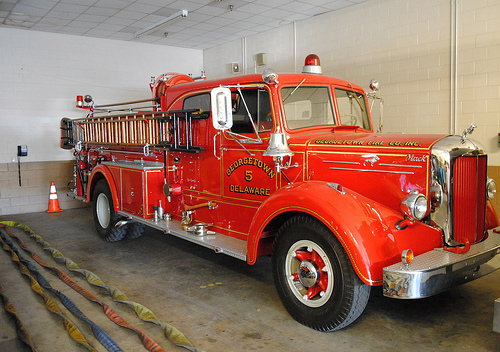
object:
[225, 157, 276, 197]
writing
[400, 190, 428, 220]
light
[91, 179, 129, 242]
back tire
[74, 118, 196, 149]
ladder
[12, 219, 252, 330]
ground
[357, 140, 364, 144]
words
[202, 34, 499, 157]
wall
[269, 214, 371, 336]
front tire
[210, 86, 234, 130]
side mirror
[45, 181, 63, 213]
cone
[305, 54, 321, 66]
light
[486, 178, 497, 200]
headlight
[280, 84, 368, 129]
windshield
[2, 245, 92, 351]
hose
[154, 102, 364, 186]
fire engine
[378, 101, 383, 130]
mirror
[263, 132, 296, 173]
bell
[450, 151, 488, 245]
grill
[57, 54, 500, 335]
fire truck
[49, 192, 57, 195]
silver stripes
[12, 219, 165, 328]
fire hoses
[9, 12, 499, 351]
garage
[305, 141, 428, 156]
stripes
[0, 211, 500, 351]
floor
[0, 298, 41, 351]
hoses